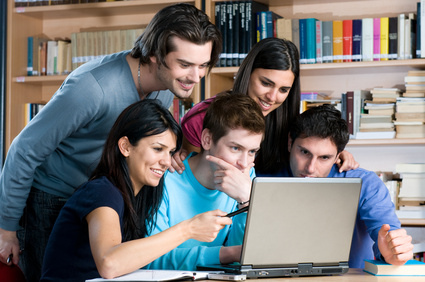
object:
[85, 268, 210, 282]
book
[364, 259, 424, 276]
book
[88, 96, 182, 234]
hair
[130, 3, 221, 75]
hair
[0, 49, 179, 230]
shirt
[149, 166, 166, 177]
smile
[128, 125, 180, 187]
face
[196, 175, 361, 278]
laptop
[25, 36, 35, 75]
books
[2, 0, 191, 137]
bookshelf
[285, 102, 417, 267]
person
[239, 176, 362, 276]
computer screen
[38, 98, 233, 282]
lady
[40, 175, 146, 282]
shirt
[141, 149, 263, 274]
shirt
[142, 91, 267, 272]
man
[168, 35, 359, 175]
lady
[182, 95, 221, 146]
pink shirt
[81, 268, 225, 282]
open book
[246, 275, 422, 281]
table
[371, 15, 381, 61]
pink book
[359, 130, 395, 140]
books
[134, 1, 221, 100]
person head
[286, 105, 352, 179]
head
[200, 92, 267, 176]
head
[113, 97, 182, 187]
head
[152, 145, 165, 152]
eye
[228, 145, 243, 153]
eye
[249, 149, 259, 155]
eye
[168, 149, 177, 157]
eye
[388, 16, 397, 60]
book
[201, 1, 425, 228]
bookcase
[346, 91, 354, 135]
book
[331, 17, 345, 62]
book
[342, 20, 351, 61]
book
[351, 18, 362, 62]
book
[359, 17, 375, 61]
book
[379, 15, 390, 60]
book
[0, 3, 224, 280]
man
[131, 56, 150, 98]
necklace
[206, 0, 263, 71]
set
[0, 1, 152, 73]
set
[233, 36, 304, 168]
hair